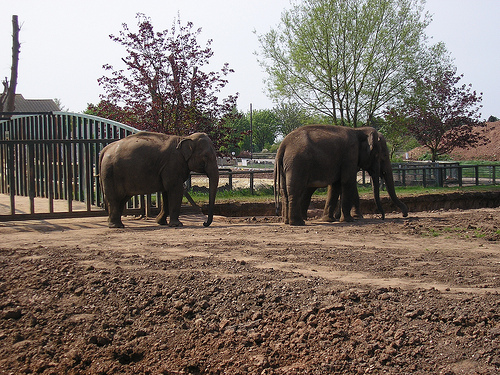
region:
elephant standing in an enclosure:
[97, 128, 220, 231]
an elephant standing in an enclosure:
[270, 124, 409, 226]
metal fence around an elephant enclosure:
[0, 111, 161, 223]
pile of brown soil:
[397, 121, 498, 161]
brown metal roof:
[0, 92, 60, 112]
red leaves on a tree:
[89, 9, 255, 157]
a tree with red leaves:
[381, 70, 498, 166]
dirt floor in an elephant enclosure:
[0, 205, 496, 373]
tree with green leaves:
[251, 0, 436, 142]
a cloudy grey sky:
[0, 0, 496, 124]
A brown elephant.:
[93, 132, 220, 230]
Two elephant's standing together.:
[271, 123, 408, 227]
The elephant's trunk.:
[203, 173, 220, 228]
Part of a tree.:
[145, 39, 184, 95]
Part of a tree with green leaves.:
[318, 18, 368, 64]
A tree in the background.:
[254, 110, 276, 140]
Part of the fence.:
[443, 166, 480, 186]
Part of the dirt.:
[240, 311, 305, 353]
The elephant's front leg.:
[339, 182, 354, 224]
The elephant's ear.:
[176, 139, 195, 161]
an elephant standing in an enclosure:
[98, 132, 217, 228]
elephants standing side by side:
[271, 123, 408, 226]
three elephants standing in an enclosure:
[95, 123, 408, 228]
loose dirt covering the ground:
[2, 205, 498, 373]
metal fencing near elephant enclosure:
[0, 108, 170, 219]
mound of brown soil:
[398, 119, 499, 159]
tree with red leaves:
[87, 9, 252, 158]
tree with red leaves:
[383, 67, 495, 160]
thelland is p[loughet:
[164, 274, 290, 369]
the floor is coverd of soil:
[208, 295, 328, 368]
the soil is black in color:
[142, 290, 232, 366]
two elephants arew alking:
[108, 137, 388, 267]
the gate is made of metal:
[50, 124, 108, 219]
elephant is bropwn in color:
[88, 138, 197, 248]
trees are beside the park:
[344, 4, 444, 118]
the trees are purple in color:
[142, 48, 222, 123]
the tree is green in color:
[297, 40, 379, 121]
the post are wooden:
[235, 162, 265, 197]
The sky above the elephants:
[0, 1, 498, 123]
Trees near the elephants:
[100, 0, 487, 162]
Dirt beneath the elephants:
[0, 212, 498, 374]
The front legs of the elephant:
[157, 195, 182, 225]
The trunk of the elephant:
[203, 169, 218, 228]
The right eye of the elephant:
[201, 149, 208, 159]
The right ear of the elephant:
[174, 137, 194, 159]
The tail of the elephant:
[275, 157, 280, 210]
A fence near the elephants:
[1, 112, 156, 219]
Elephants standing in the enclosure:
[98, 124, 408, 229]